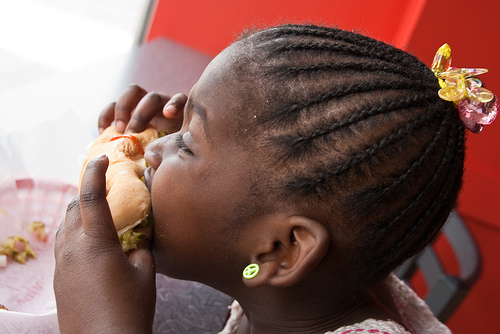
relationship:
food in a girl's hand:
[83, 125, 178, 259] [21, 148, 165, 324]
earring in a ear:
[234, 256, 262, 286] [207, 200, 352, 298]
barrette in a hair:
[431, 43, 498, 134] [253, 25, 471, 327]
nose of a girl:
[135, 126, 180, 174] [104, 17, 496, 327]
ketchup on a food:
[105, 126, 140, 147] [81, 125, 178, 258]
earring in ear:
[242, 260, 261, 280] [245, 214, 330, 291]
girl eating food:
[124, 10, 438, 331] [74, 90, 194, 265]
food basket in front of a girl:
[6, 164, 101, 327] [118, 35, 477, 329]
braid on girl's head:
[265, 84, 376, 176] [107, 8, 485, 332]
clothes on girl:
[360, 276, 439, 330] [130, 14, 485, 332]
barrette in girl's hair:
[423, 43, 498, 135] [123, 36, 439, 318]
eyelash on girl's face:
[165, 128, 204, 161] [130, 50, 300, 270]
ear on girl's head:
[219, 215, 335, 302] [123, 24, 479, 314]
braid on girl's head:
[254, 50, 409, 87] [153, 21, 474, 329]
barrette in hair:
[431, 43, 498, 134] [325, 24, 487, 259]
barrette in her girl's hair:
[431, 43, 498, 134] [209, 23, 500, 260]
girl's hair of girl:
[209, 23, 500, 260] [53, 14, 496, 328]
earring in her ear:
[242, 260, 261, 280] [245, 214, 330, 291]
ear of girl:
[245, 214, 330, 291] [53, 14, 496, 328]